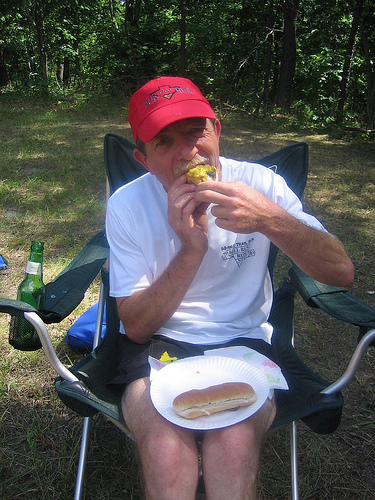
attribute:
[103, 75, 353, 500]
man — sitting, eating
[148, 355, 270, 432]
paper plate — white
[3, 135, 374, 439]
chair — green, blue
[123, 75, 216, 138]
cap — red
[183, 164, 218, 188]
food — yellow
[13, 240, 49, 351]
beer bottle — green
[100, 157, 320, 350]
shirt — white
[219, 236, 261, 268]
emblem — black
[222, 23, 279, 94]
leaves — green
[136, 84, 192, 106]
logo — blue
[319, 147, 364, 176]
grass — brown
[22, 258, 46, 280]
label — white